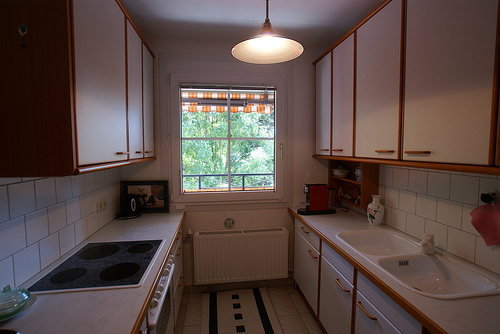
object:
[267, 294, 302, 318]
tiles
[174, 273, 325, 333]
floor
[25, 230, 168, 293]
top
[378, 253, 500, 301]
sink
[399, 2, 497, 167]
cabinet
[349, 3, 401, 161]
cabinet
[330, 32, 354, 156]
cabinet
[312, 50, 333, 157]
cabinet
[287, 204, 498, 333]
countertop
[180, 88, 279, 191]
window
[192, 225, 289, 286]
unit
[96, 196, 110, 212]
outlet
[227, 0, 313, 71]
light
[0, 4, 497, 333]
kitchen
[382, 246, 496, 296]
sink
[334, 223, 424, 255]
sink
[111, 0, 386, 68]
ceiling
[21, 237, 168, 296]
burners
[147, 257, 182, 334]
stove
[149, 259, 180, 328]
handle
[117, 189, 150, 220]
kettle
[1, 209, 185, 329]
counter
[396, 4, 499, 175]
frame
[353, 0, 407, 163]
frame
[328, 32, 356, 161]
frame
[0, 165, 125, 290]
wall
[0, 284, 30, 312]
dish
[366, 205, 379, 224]
design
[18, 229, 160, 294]
stovetop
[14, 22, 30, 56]
picture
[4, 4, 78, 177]
end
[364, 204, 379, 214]
flower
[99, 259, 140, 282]
element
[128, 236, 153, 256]
element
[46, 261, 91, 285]
element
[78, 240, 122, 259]
element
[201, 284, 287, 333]
runner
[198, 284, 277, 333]
stripes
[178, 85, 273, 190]
view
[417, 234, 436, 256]
faucet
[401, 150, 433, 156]
cabinet handle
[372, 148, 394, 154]
cabinet handle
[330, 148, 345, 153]
cabinet handle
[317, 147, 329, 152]
cabinet handle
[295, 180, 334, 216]
appliance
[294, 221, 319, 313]
cabinet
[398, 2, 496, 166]
door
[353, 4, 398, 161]
door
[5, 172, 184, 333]
backsplash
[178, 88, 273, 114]
over hang